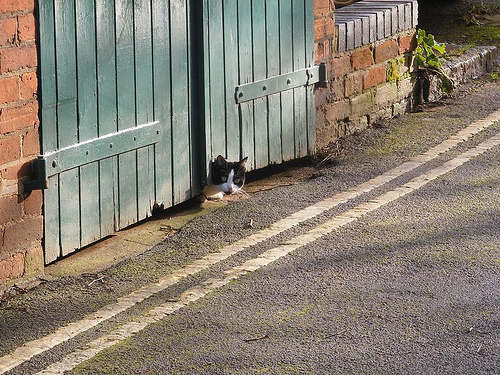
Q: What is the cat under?
A: A green door.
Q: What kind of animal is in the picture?
A: A cat.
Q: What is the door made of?
A: Wood.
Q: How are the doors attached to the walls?
A: Hinges.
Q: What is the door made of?
A: Wood.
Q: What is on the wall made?
A: Bricks.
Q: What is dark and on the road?
A: Shadow.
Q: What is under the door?
A: Cat head.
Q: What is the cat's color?
A: Black and white.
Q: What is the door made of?
A: Green slats.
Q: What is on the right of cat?
A: A door.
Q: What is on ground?
A: Lines.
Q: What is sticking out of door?
A: Cat's head.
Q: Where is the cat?
A: Under the door.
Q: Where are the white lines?
A: On the road.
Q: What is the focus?
A: Cat peeking head under gate.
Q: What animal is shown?
A: Cat.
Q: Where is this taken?
A: Street.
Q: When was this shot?
A: Daytime.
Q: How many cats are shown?
A: 1.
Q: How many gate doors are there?
A: 2.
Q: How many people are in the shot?
A: 0.